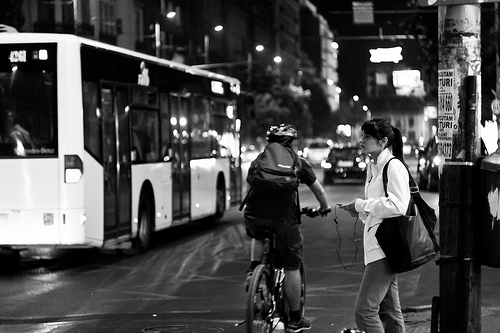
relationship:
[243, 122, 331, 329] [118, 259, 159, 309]
bicyclist waiting on street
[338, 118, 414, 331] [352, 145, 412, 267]
girl has shirt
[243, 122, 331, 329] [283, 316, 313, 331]
bicyclist has shoe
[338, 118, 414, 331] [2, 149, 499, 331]
girl standing near street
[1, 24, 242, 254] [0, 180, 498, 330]
bus on street